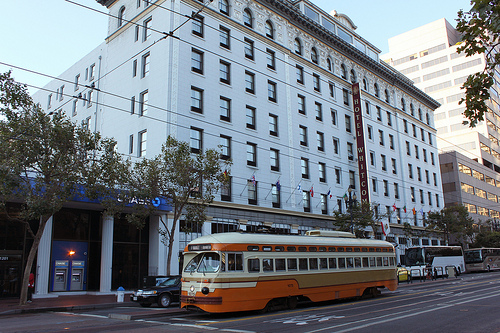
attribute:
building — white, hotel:
[1, 0, 450, 238]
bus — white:
[404, 244, 466, 279]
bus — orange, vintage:
[177, 230, 400, 312]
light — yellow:
[66, 249, 76, 256]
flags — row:
[215, 157, 450, 224]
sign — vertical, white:
[350, 82, 372, 218]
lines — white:
[217, 271, 497, 328]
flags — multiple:
[223, 170, 426, 220]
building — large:
[14, 1, 452, 283]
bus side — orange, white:
[221, 239, 400, 316]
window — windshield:
[183, 248, 218, 273]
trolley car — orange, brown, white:
[182, 230, 398, 315]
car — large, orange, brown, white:
[204, 217, 403, 299]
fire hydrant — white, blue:
[115, 285, 124, 305]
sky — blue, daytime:
[18, 16, 87, 46]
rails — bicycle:
[400, 242, 463, 280]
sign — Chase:
[150, 195, 173, 210]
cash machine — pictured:
[51, 256, 70, 294]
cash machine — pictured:
[69, 257, 85, 287]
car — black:
[127, 272, 184, 308]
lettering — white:
[355, 83, 370, 213]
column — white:
[97, 210, 116, 291]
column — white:
[32, 205, 54, 300]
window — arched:
[241, 4, 253, 23]